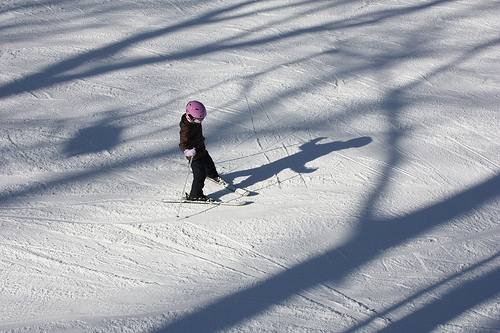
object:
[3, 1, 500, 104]
dark shadow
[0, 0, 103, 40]
shadow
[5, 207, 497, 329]
snow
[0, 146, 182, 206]
shadow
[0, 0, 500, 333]
slope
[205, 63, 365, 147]
shadow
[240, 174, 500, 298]
shadow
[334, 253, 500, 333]
shadow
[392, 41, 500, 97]
shadow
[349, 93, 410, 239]
shadow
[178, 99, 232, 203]
person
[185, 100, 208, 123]
helmet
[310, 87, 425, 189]
snow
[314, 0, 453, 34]
shadow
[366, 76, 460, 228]
snow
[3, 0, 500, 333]
tree shadows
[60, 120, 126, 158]
shadow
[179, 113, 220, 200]
clothes